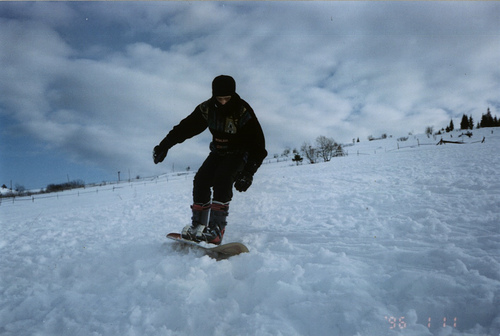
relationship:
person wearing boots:
[148, 70, 273, 246] [186, 200, 229, 246]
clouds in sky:
[2, 2, 498, 132] [4, 4, 494, 182]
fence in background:
[3, 135, 499, 202] [6, 113, 497, 227]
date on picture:
[380, 310, 463, 331] [2, 4, 498, 304]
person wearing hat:
[148, 70, 273, 246] [208, 73, 238, 99]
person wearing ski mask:
[148, 70, 273, 246] [209, 92, 237, 110]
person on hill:
[148, 70, 273, 246] [2, 121, 497, 326]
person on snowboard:
[148, 70, 273, 246] [166, 228, 249, 259]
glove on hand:
[152, 145, 170, 165] [151, 144, 171, 163]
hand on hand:
[153, 145, 168, 164] [233, 167, 253, 193]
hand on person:
[151, 144, 171, 163] [148, 70, 273, 246]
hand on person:
[233, 167, 253, 193] [148, 70, 273, 246]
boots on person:
[186, 200, 229, 246] [148, 70, 273, 246]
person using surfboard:
[148, 70, 273, 246] [166, 228, 249, 259]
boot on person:
[205, 199, 229, 244] [148, 70, 273, 246]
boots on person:
[166, 200, 209, 246] [148, 70, 273, 246]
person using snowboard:
[148, 70, 273, 246] [166, 228, 249, 259]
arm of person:
[236, 109, 268, 194] [148, 70, 273, 246]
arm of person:
[152, 102, 212, 165] [148, 70, 273, 246]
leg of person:
[209, 149, 243, 249] [148, 70, 273, 246]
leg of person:
[188, 149, 215, 243] [148, 70, 273, 246]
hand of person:
[233, 167, 253, 193] [148, 70, 273, 246]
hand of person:
[151, 144, 171, 163] [148, 70, 273, 246]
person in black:
[148, 70, 273, 246] [149, 73, 269, 241]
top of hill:
[388, 115, 499, 146] [2, 121, 497, 326]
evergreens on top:
[441, 109, 500, 133] [388, 115, 499, 146]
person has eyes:
[148, 70, 273, 246] [215, 95, 232, 101]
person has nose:
[148, 70, 273, 246] [219, 98, 226, 105]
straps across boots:
[189, 221, 226, 239] [186, 200, 229, 246]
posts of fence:
[9, 191, 151, 202] [3, 135, 499, 202]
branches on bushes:
[294, 133, 347, 153] [297, 134, 353, 169]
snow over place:
[2, 121, 497, 326] [21, 163, 483, 328]